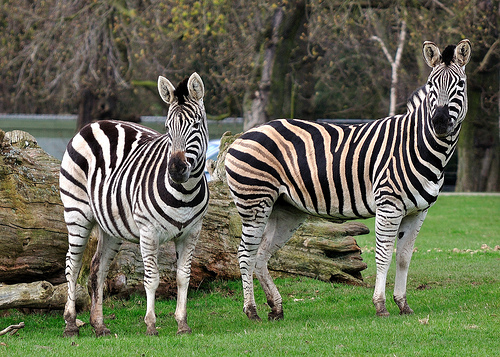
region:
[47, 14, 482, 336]
two zebras in this shot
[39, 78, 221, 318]
this zebra looks fairly new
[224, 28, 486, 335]
this zebra is young as well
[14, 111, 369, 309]
a huge tree trunk behind the zebras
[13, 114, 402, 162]
water is in the area by the zebras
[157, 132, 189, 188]
this zebra has a pink nose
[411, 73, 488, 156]
this zebra's nose is black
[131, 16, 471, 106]
both of these zebras have a patch of black hair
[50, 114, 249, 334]
stripes are on a zebra's body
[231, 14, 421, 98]
forest are behind the zebra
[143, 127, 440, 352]
two zebras are in the picture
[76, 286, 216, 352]
the hoofs are black in color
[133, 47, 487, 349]
the zebras are looking in one direction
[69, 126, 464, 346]
zebras are standing next to a log of tree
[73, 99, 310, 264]
the zebras are black and white stripped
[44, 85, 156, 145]
the river 9is beside the forst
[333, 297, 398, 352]
the grasses are green in color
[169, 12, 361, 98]
the trees are next to the river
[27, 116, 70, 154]
the water is colorles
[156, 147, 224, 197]
the mouth is black incolor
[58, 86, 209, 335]
the zebra is black and white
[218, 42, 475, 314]
the zebra is black and white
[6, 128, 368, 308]
the log is huge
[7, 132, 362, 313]
the log is grey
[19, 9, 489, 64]
trees are in the background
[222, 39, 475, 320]
the zebra is looking at the camera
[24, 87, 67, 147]
water is in the background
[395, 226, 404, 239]
the spot is black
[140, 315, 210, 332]
the hooves are grey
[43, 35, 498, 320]
the zebras are two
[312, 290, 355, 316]
this is the grass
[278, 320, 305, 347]
the grass is green in color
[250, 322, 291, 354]
the grass is short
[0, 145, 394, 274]
this is a log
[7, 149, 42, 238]
the log is big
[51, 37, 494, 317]
these are two zebras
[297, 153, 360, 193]
the fur is black and white in color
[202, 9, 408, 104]
these are some trees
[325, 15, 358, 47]
the trees are tall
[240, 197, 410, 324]
these are the feet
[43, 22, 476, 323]
these are the zebras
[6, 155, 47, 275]
this is a fallen tree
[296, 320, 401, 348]
this is the grass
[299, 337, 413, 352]
the grass is green in colour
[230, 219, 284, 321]
these are the limbs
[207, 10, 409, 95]
these are trees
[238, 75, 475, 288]
the zebra is black and white in colour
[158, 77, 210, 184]
this is the head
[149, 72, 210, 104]
these are the ears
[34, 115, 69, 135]
this is the water